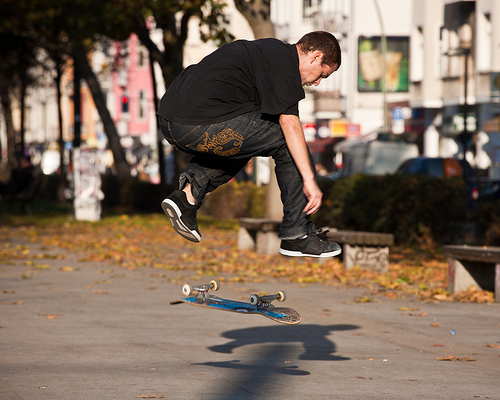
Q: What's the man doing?
A: Skateboarding.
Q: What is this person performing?
A: Skateboard trick.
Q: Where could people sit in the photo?
A: On benches.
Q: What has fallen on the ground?
A: Leaves.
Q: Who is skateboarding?
A: A man.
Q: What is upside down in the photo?
A: A skateboard.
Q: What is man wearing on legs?
A: Jeans.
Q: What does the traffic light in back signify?
A: Stop.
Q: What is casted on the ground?
A: A shadow.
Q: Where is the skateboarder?
A: In a city park.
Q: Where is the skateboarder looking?
A: Down.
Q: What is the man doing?
A: Skateboarding.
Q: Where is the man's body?
A: In the air.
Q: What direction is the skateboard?
A: Upside down.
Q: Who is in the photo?
A: A man.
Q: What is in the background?
A: Street.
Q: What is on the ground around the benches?
A: Leaves.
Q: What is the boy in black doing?
A: Skateboarding.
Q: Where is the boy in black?
A: In mid-air.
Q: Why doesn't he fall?
A: He practices.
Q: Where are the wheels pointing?
A: Upward.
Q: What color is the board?
A: Blue.